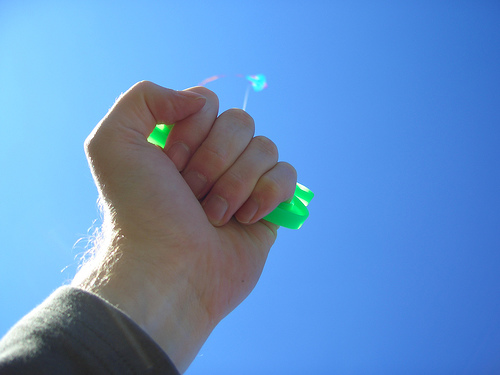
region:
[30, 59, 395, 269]
a hand in the air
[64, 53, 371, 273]
a hand closed around handle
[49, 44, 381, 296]
a hand closed around green handle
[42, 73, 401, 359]
a man holding a kite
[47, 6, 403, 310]
a hand holding a kite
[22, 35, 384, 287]
a hand holding a kite handle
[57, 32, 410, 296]
a hand holding green kite handle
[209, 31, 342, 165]
a kite in the sky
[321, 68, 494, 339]
skies that are clear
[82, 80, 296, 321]
man's hand grasping green band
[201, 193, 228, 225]
man's pink fingernail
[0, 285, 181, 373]
part of man's shirt sleeve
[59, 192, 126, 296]
man's arm hairs glowing in sun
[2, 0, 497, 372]
clear blue beautiful sky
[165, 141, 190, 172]
man's fingernail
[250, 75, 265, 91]
green circle glowing in the sun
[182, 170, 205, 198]
a man's fingernail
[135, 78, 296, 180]
a man's knuckles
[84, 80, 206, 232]
a man's thumb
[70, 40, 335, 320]
A hand holding a kite string.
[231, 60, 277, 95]
The kite is high in the sky.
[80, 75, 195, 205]
The thumb is bent.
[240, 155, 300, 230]
The pinky finger is the shortest finger on the hand.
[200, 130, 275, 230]
The ring finger is next to the pinky.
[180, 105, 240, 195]
The middle finger is the middle finger on the hand.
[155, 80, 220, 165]
The thumb is touching the index finger.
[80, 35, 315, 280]
Five fingers are on the hand.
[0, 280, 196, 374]
The shirt sleeve is grey.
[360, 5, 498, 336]
The sky is blue.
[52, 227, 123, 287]
hair on the hand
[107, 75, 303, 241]
fingers wrapped around a green object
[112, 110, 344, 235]
bright green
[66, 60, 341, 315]
hand making a fist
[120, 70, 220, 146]
thumb resting over the finger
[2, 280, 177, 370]
shirt sleeve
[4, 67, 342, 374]
hand raised in the air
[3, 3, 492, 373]
bright blue sky with no clouds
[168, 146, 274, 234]
short fingernails on the fingers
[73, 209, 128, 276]
light shining on the arm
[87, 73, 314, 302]
The hand holding a green object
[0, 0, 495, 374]
The blue colored space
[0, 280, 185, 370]
The partially hidden dark cloth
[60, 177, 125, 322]
The wrist's hairy region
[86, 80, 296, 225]
The five folded fingers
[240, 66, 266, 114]
The protruding region of an object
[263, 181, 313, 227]
The folded green part on the right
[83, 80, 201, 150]
The folded thumb region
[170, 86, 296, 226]
The clear finger nails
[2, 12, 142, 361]
The brightened blue region on the left